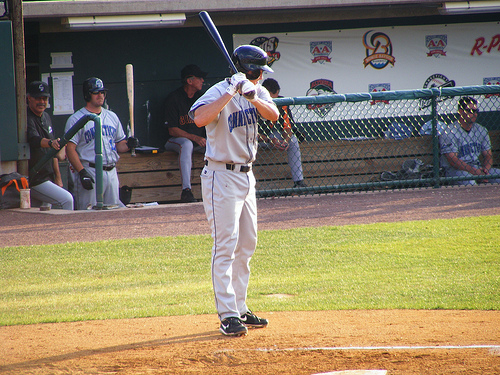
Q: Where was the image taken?
A: It was taken at the field.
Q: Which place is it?
A: It is a field.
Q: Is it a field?
A: Yes, it is a field.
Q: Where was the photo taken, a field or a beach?
A: It was taken at a field.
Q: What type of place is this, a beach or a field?
A: It is a field.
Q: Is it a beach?
A: No, it is a field.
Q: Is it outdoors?
A: Yes, it is outdoors.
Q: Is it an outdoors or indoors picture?
A: It is outdoors.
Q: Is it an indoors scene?
A: No, it is outdoors.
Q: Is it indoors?
A: No, it is outdoors.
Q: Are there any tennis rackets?
A: No, there are no tennis rackets.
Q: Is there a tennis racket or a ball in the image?
A: No, there are no rackets or balls.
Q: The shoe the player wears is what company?
A: The shoe is nike.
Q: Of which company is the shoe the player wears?
A: The shoe is nike.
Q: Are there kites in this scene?
A: No, there are no kites.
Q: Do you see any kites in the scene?
A: No, there are no kites.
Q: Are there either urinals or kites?
A: No, there are no kites or urinals.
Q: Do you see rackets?
A: No, there are no rackets.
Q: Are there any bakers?
A: No, there are no bakers.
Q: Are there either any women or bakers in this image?
A: No, there are no bakers or women.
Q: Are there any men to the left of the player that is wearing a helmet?
A: Yes, there is a man to the left of the player.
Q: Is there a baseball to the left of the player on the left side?
A: No, there is a man to the left of the player.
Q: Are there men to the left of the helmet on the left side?
A: Yes, there is a man to the left of the helmet.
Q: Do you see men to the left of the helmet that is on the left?
A: Yes, there is a man to the left of the helmet.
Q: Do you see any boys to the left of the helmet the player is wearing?
A: No, there is a man to the left of the helmet.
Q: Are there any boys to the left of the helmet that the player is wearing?
A: No, there is a man to the left of the helmet.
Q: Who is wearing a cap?
A: The man is wearing a cap.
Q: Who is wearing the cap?
A: The man is wearing a cap.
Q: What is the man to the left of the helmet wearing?
A: The man is wearing a cap.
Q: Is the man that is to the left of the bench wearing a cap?
A: Yes, the man is wearing a cap.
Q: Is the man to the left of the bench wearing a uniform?
A: No, the man is wearing a cap.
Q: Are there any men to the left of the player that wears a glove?
A: Yes, there is a man to the left of the player.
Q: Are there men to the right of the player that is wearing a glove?
A: No, the man is to the left of the player.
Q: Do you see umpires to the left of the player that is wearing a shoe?
A: No, there is a man to the left of the player.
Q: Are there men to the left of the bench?
A: Yes, there is a man to the left of the bench.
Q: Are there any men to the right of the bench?
A: No, the man is to the left of the bench.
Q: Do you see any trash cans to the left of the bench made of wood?
A: No, there is a man to the left of the bench.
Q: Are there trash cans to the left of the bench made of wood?
A: No, there is a man to the left of the bench.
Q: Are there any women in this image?
A: No, there are no women.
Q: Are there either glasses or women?
A: No, there are no women or glasses.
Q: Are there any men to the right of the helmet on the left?
A: Yes, there is a man to the right of the helmet.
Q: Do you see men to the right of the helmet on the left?
A: Yes, there is a man to the right of the helmet.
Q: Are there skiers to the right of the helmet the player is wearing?
A: No, there is a man to the right of the helmet.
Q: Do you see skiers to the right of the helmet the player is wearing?
A: No, there is a man to the right of the helmet.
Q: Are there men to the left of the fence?
A: Yes, there is a man to the left of the fence.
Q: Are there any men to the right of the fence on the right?
A: No, the man is to the left of the fence.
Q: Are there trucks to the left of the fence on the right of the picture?
A: No, there is a man to the left of the fence.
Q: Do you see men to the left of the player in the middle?
A: Yes, there is a man to the left of the player.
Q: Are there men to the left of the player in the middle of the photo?
A: Yes, there is a man to the left of the player.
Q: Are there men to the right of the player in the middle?
A: No, the man is to the left of the player.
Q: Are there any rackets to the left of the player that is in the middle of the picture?
A: No, there is a man to the left of the player.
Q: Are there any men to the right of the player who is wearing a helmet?
A: Yes, there is a man to the right of the player.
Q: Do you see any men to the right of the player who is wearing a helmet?
A: Yes, there is a man to the right of the player.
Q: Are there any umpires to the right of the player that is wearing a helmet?
A: No, there is a man to the right of the player.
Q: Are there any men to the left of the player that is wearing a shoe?
A: Yes, there is a man to the left of the player.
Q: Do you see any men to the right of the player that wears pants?
A: No, the man is to the left of the player.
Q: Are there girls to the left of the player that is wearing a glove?
A: No, there is a man to the left of the player.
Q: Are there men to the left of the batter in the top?
A: Yes, there is a man to the left of the batter.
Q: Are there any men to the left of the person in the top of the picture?
A: Yes, there is a man to the left of the batter.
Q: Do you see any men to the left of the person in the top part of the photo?
A: Yes, there is a man to the left of the batter.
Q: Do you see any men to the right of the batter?
A: No, the man is to the left of the batter.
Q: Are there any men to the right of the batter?
A: No, the man is to the left of the batter.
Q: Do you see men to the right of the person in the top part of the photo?
A: No, the man is to the left of the batter.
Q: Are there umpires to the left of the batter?
A: No, there is a man to the left of the batter.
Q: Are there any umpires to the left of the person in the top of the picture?
A: No, there is a man to the left of the batter.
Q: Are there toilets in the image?
A: No, there are no toilets.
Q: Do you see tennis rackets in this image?
A: No, there are no tennis rackets.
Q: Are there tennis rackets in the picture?
A: No, there are no tennis rackets.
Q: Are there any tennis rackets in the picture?
A: No, there are no tennis rackets.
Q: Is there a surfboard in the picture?
A: No, there are no surfboards.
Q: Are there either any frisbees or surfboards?
A: No, there are no surfboards or frisbees.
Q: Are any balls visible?
A: No, there are no balls.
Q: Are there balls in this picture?
A: No, there are no balls.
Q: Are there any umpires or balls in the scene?
A: No, there are no balls or umpires.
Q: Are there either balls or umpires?
A: No, there are no balls or umpires.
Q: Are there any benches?
A: Yes, there is a bench.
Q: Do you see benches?
A: Yes, there is a bench.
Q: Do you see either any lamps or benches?
A: Yes, there is a bench.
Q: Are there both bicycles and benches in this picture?
A: No, there is a bench but no bikes.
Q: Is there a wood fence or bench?
A: Yes, there is a wood bench.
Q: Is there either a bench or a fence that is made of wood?
A: Yes, the bench is made of wood.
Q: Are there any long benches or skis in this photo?
A: Yes, there is a long bench.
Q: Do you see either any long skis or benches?
A: Yes, there is a long bench.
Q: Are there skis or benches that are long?
A: Yes, the bench is long.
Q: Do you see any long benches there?
A: Yes, there is a long bench.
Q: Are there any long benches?
A: Yes, there is a long bench.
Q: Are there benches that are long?
A: Yes, there is a bench that is long.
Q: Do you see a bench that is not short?
A: Yes, there is a long bench.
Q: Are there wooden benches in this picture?
A: Yes, there is a wood bench.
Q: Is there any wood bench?
A: Yes, there is a wood bench.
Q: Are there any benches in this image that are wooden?
A: Yes, there is a bench that is wooden.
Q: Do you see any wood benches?
A: Yes, there is a bench that is made of wood.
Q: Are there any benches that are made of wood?
A: Yes, there is a bench that is made of wood.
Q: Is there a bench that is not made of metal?
A: Yes, there is a bench that is made of wood.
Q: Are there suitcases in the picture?
A: No, there are no suitcases.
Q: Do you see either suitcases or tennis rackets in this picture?
A: No, there are no suitcases or tennis rackets.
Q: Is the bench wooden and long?
A: Yes, the bench is wooden and long.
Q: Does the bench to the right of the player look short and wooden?
A: No, the bench is wooden but long.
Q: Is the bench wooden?
A: Yes, the bench is wooden.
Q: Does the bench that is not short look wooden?
A: Yes, the bench is wooden.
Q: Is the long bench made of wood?
A: Yes, the bench is made of wood.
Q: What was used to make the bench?
A: The bench is made of wood.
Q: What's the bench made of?
A: The bench is made of wood.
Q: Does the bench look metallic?
A: No, the bench is wooden.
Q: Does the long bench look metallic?
A: No, the bench is wooden.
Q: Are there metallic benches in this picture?
A: No, there is a bench but it is wooden.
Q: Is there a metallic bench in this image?
A: No, there is a bench but it is wooden.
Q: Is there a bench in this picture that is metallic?
A: No, there is a bench but it is wooden.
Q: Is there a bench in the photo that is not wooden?
A: No, there is a bench but it is wooden.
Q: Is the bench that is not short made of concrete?
A: No, the bench is made of wood.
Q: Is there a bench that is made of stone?
A: No, there is a bench but it is made of wood.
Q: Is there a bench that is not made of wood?
A: No, there is a bench but it is made of wood.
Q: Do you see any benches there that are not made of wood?
A: No, there is a bench but it is made of wood.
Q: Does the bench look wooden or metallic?
A: The bench is wooden.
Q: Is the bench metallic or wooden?
A: The bench is wooden.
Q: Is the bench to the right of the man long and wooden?
A: Yes, the bench is long and wooden.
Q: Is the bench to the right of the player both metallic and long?
A: No, the bench is long but wooden.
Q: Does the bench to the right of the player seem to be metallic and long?
A: No, the bench is long but wooden.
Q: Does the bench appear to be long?
A: Yes, the bench is long.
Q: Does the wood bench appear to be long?
A: Yes, the bench is long.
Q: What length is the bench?
A: The bench is long.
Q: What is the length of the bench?
A: The bench is long.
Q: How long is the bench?
A: The bench is long.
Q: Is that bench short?
A: No, the bench is long.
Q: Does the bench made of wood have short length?
A: No, the bench is long.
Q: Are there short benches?
A: No, there is a bench but it is long.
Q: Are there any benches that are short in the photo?
A: No, there is a bench but it is long.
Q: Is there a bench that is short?
A: No, there is a bench but it is long.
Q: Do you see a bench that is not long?
A: No, there is a bench but it is long.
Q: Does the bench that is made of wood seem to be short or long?
A: The bench is long.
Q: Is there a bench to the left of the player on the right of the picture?
A: Yes, there is a bench to the left of the player.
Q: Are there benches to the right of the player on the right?
A: No, the bench is to the left of the player.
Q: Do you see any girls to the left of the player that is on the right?
A: No, there is a bench to the left of the player.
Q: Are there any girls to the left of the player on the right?
A: No, there is a bench to the left of the player.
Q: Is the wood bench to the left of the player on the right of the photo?
A: Yes, the bench is to the left of the player.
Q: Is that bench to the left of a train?
A: No, the bench is to the left of the player.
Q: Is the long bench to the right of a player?
A: No, the bench is to the left of a player.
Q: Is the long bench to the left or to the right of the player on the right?
A: The bench is to the left of the player.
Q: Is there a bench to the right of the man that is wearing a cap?
A: Yes, there is a bench to the right of the man.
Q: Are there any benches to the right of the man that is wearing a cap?
A: Yes, there is a bench to the right of the man.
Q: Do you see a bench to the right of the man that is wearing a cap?
A: Yes, there is a bench to the right of the man.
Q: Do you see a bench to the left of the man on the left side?
A: No, the bench is to the right of the man.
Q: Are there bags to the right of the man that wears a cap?
A: No, there is a bench to the right of the man.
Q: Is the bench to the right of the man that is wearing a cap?
A: Yes, the bench is to the right of the man.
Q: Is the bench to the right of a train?
A: No, the bench is to the right of the man.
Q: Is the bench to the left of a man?
A: No, the bench is to the right of a man.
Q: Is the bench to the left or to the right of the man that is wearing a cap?
A: The bench is to the right of the man.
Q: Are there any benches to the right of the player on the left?
A: Yes, there is a bench to the right of the player.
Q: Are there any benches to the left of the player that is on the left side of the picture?
A: No, the bench is to the right of the player.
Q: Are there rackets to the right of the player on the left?
A: No, there is a bench to the right of the player.